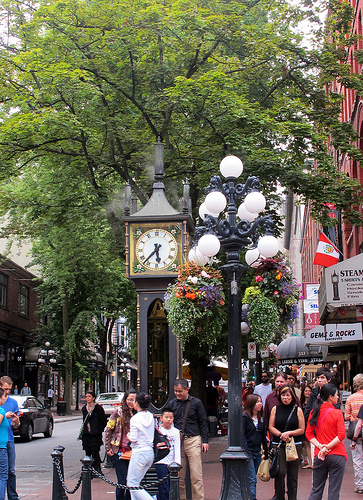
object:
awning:
[276, 334, 326, 361]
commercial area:
[0, 251, 363, 499]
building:
[283, 0, 362, 452]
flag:
[313, 228, 340, 268]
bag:
[76, 403, 97, 441]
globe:
[219, 154, 244, 178]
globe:
[258, 234, 279, 258]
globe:
[188, 245, 208, 266]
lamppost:
[37, 341, 57, 408]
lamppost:
[187, 153, 280, 498]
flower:
[199, 282, 221, 308]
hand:
[154, 243, 161, 263]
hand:
[143, 244, 162, 265]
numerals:
[141, 240, 145, 243]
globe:
[245, 192, 267, 214]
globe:
[205, 192, 227, 213]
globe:
[198, 234, 221, 257]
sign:
[331, 268, 363, 303]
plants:
[163, 257, 230, 349]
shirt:
[306, 401, 347, 457]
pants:
[176, 435, 206, 500]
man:
[162, 378, 210, 499]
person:
[126, 391, 154, 499]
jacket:
[128, 410, 155, 452]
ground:
[0, 393, 363, 498]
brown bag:
[269, 441, 287, 480]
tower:
[121, 136, 197, 498]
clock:
[135, 228, 178, 272]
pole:
[317, 228, 346, 257]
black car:
[9, 393, 54, 440]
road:
[0, 411, 108, 500]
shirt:
[343, 388, 363, 421]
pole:
[227, 295, 243, 446]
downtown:
[2, 2, 362, 497]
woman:
[306, 381, 349, 500]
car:
[96, 392, 125, 416]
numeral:
[147, 233, 152, 238]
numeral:
[154, 231, 159, 236]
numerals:
[138, 248, 143, 252]